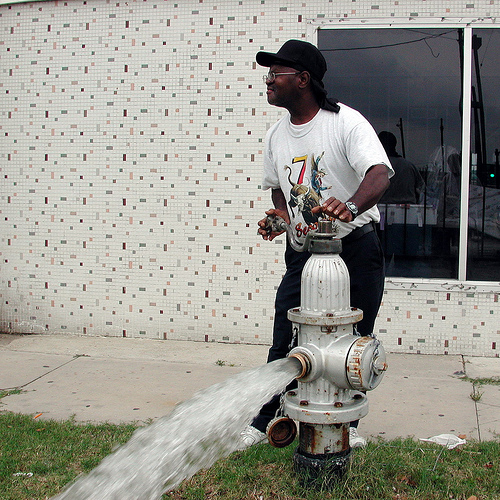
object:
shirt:
[262, 101, 396, 253]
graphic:
[284, 151, 341, 238]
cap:
[266, 417, 297, 449]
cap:
[345, 336, 387, 392]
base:
[293, 421, 351, 492]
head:
[266, 39, 328, 105]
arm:
[344, 165, 390, 221]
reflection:
[374, 117, 500, 282]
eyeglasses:
[262, 71, 300, 82]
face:
[266, 64, 288, 101]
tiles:
[57, 69, 157, 152]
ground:
[0, 333, 500, 500]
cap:
[256, 39, 328, 82]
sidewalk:
[0, 332, 500, 442]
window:
[317, 28, 499, 283]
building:
[0, 0, 498, 359]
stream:
[45, 355, 303, 500]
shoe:
[349, 426, 367, 448]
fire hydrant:
[264, 212, 388, 496]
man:
[235, 39, 395, 452]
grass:
[0, 409, 500, 499]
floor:
[0, 355, 480, 442]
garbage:
[419, 433, 467, 450]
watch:
[344, 201, 358, 222]